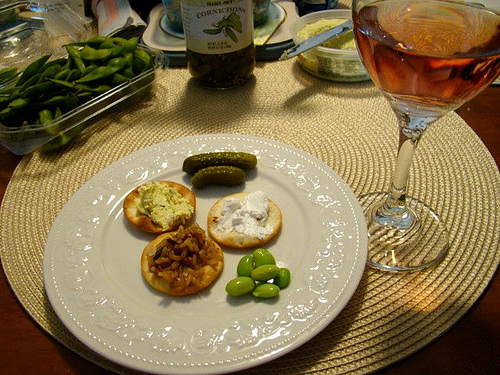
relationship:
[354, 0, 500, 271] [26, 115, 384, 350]
glass under plate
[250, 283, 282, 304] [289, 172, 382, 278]
bean on plate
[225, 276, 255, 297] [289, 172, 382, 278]
bean on plate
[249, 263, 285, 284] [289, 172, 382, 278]
bean on plate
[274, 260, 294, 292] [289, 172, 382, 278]
bean on plate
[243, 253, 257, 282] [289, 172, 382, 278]
bean on plate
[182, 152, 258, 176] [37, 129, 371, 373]
pickles on plate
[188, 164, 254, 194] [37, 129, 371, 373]
pickle on plate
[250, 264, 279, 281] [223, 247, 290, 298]
bean next to beans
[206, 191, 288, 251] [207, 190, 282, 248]
cracker with cracker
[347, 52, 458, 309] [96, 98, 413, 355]
glass sitting next to a plate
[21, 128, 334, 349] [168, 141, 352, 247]
plate with pickles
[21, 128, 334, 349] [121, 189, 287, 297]
plate with crackers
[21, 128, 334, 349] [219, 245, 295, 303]
plate with beans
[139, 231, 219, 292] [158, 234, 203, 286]
cracker with rice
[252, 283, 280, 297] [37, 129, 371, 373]
bean on plate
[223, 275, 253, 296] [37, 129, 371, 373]
bean on plate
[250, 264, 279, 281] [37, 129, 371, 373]
bean on plate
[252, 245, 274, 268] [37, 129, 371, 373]
bean on plate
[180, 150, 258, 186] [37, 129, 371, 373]
pickles on plate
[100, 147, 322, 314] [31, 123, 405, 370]
food on white plate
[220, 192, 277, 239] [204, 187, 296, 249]
cheese on cracker